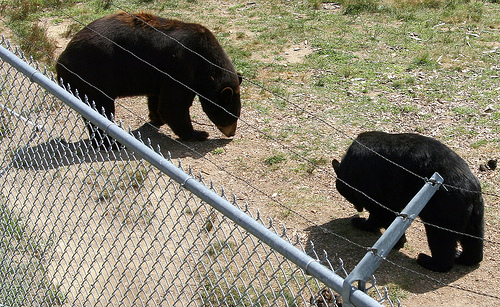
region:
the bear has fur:
[231, 89, 489, 265]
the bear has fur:
[310, 78, 455, 218]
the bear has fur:
[360, 54, 484, 300]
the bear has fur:
[326, 129, 494, 214]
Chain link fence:
[30, 53, 126, 203]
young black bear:
[326, 109, 494, 266]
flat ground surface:
[251, 8, 432, 115]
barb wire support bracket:
[337, 131, 459, 289]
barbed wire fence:
[247, 66, 317, 223]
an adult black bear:
[50, 7, 265, 152]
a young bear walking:
[330, 115, 491, 270]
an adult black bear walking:
[51, 5, 271, 140]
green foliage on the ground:
[335, 1, 495, 96]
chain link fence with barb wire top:
[53, 81, 370, 297]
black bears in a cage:
[24, 6, 489, 291]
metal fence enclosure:
[14, 35, 376, 296]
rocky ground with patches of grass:
[56, 11, 448, 247]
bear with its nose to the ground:
[41, 4, 268, 178]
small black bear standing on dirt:
[305, 104, 492, 283]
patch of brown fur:
[101, 5, 201, 57]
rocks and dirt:
[271, 19, 468, 126]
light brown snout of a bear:
[191, 66, 271, 168]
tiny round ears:
[210, 61, 249, 100]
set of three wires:
[85, 13, 392, 253]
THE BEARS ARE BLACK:
[43, 12, 485, 290]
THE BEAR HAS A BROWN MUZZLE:
[215, 120, 240, 141]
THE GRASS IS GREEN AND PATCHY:
[0, 3, 498, 290]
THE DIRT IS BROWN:
[1, 9, 498, 296]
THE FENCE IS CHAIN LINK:
[1, 32, 408, 305]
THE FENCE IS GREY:
[0, 35, 410, 305]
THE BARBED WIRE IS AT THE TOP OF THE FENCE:
[0, 0, 495, 303]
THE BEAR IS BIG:
[53, 7, 250, 151]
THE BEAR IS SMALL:
[328, 125, 494, 280]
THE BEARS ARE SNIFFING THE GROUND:
[56, 6, 493, 273]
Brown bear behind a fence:
[332, 125, 483, 266]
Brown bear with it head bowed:
[48, 11, 270, 161]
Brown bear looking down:
[328, 127, 481, 255]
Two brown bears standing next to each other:
[75, 18, 499, 270]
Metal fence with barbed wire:
[84, 73, 332, 183]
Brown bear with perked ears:
[53, 5, 252, 145]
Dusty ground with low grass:
[319, 29, 474, 102]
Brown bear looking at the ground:
[63, 8, 258, 144]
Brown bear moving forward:
[328, 120, 488, 272]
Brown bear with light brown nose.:
[53, 23, 260, 141]